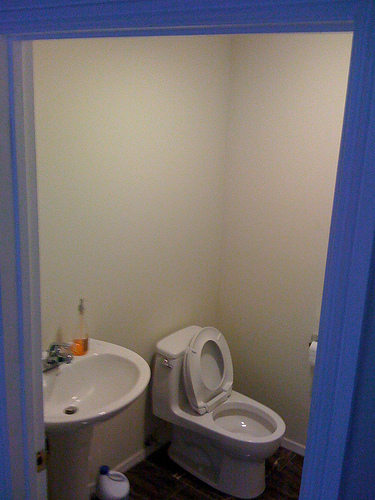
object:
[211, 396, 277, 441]
bowl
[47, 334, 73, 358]
handle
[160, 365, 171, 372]
plunger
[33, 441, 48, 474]
door jamb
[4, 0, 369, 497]
wall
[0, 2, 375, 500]
door frame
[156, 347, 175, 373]
apparatus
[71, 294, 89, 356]
container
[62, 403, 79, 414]
drain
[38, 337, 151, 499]
sink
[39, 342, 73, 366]
faucet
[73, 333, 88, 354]
soap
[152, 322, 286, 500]
porcelain toilet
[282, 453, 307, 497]
floor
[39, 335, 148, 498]
bathroom sink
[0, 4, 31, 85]
door trim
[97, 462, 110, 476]
cap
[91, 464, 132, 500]
bleach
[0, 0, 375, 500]
bathroom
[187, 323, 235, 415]
seat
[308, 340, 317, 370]
paper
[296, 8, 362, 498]
curtain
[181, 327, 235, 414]
lid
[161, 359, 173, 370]
handle